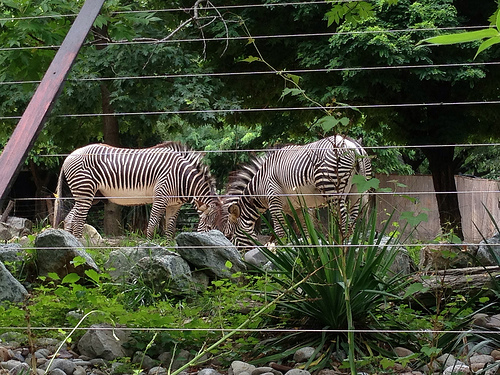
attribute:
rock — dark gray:
[75, 321, 131, 362]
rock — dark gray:
[37, 356, 74, 373]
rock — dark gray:
[145, 362, 167, 373]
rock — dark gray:
[37, 343, 53, 358]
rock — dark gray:
[33, 353, 46, 363]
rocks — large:
[3, 211, 275, 319]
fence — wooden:
[457, 173, 498, 238]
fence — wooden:
[378, 170, 438, 237]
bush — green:
[246, 179, 440, 374]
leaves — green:
[422, 64, 472, 87]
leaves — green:
[369, 41, 396, 58]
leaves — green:
[337, 15, 364, 29]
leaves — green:
[164, 88, 197, 100]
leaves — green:
[7, 55, 29, 77]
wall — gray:
[377, 175, 438, 238]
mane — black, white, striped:
[176, 143, 220, 185]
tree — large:
[316, 7, 490, 247]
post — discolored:
[0, 0, 109, 216]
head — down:
[189, 191, 244, 248]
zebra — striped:
[223, 130, 373, 248]